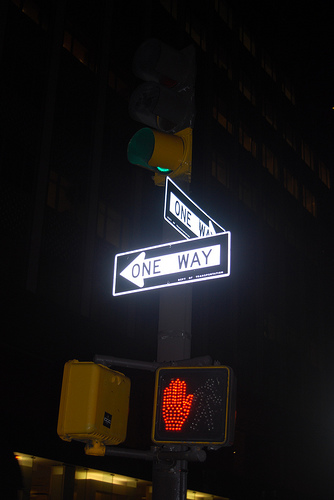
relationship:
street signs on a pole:
[106, 238, 229, 300] [155, 177, 194, 495]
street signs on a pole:
[163, 177, 225, 235] [155, 177, 194, 495]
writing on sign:
[178, 270, 224, 281] [109, 228, 235, 299]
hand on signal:
[152, 385, 208, 421] [142, 358, 253, 431]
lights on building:
[72, 467, 147, 488] [17, 444, 146, 492]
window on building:
[232, 123, 259, 158] [211, 31, 330, 333]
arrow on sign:
[117, 243, 239, 279] [103, 226, 245, 300]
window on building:
[35, 448, 91, 494] [24, 463, 142, 491]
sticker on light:
[102, 406, 113, 430] [67, 359, 129, 442]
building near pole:
[11, 58, 332, 313] [136, 128, 227, 350]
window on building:
[210, 105, 233, 135] [0, 31, 324, 498]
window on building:
[241, 127, 258, 159] [0, 31, 324, 498]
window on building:
[262, 145, 278, 181] [0, 31, 324, 498]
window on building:
[283, 166, 298, 199] [0, 31, 324, 498]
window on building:
[303, 185, 316, 215] [0, 31, 324, 498]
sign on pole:
[147, 360, 234, 451] [90, 92, 253, 493]